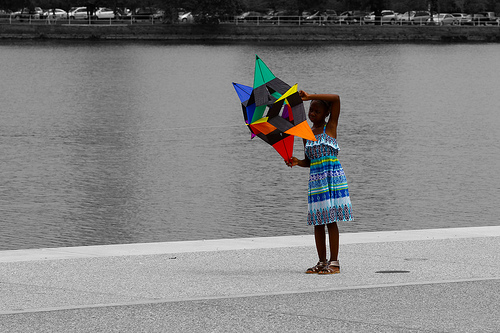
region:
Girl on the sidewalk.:
[231, 49, 388, 296]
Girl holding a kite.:
[211, 55, 348, 177]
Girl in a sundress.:
[228, 53, 385, 331]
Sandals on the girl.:
[285, 251, 367, 296]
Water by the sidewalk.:
[73, 200, 273, 306]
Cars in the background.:
[121, 2, 343, 35]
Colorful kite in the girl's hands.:
[201, 34, 348, 172]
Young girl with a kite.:
[223, 44, 353, 304]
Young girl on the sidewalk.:
[224, 40, 400, 320]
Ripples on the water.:
[71, 67, 156, 184]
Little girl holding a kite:
[209, 34, 365, 294]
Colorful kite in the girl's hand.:
[215, 28, 311, 184]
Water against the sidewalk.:
[93, 168, 260, 277]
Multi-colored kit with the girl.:
[202, 28, 372, 297]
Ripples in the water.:
[71, 93, 444, 283]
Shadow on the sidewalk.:
[363, 216, 440, 299]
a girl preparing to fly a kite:
[222, 52, 362, 276]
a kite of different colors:
[233, 49, 311, 169]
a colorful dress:
[308, 131, 350, 228]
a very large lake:
[8, 39, 257, 241]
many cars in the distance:
[11, 4, 478, 27]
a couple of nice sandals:
[308, 259, 340, 277]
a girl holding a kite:
[233, 56, 367, 276]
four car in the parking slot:
[15, 4, 131, 22]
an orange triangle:
[286, 119, 318, 143]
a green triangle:
[253, 55, 275, 88]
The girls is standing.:
[301, 82, 359, 282]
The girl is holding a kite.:
[227, 45, 367, 277]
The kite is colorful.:
[225, 58, 320, 162]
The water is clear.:
[6, 40, 486, 235]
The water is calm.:
[15, 45, 484, 215]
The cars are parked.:
[12, 4, 491, 34]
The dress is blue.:
[298, 130, 371, 233]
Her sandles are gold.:
[300, 261, 352, 282]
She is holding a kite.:
[227, 52, 369, 279]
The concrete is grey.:
[22, 228, 470, 329]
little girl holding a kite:
[219, 39, 373, 291]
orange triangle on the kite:
[283, 121, 318, 145]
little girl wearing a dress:
[287, 84, 374, 286]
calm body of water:
[3, 33, 499, 252]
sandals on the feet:
[301, 252, 346, 277]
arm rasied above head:
[302, 83, 342, 134]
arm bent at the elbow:
[302, 85, 349, 126]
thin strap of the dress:
[320, 118, 328, 130]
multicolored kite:
[222, 38, 321, 184]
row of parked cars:
[12, 2, 125, 24]